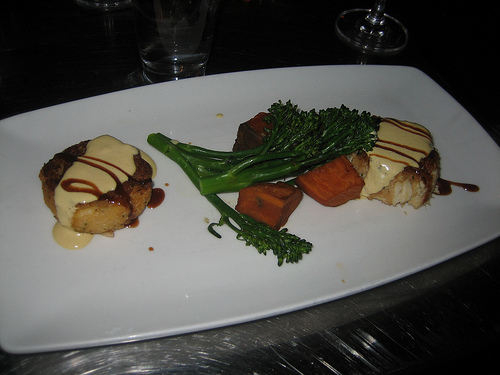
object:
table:
[0, 7, 500, 370]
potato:
[235, 182, 303, 231]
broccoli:
[198, 99, 383, 196]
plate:
[0, 64, 498, 355]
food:
[37, 134, 158, 234]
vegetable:
[198, 98, 382, 197]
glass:
[334, 0, 410, 53]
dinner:
[38, 100, 445, 266]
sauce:
[50, 134, 157, 251]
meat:
[344, 118, 441, 210]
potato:
[232, 112, 274, 153]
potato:
[296, 154, 366, 207]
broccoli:
[145, 132, 314, 268]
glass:
[139, 0, 208, 83]